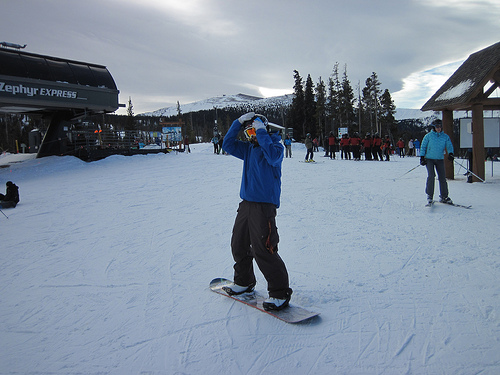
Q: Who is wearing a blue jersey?
A: A boy.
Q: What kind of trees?
A: Pine.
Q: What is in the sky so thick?
A: Clouds.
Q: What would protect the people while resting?
A: The shed.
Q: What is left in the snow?
A: Tracks.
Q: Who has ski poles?
A: A man.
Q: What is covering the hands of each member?
A: Gloves.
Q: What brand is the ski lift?
A: Zephyr Express.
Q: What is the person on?
A: Snowboard.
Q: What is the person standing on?
A: Skis.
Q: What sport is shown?
A: Snowboarding.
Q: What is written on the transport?
A: Zephyr Express.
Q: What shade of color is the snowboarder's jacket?
A: Blue.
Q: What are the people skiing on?
A: Snow.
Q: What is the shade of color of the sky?
A: Grey.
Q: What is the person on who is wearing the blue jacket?
A: A snowboard.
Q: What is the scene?
A: A ski resort.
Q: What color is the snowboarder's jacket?
A: Blue.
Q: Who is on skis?
A: A person with a teal coat.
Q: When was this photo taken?
A: During the daytime.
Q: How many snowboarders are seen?
A: One.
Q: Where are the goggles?
A: On the snowboarder's face.